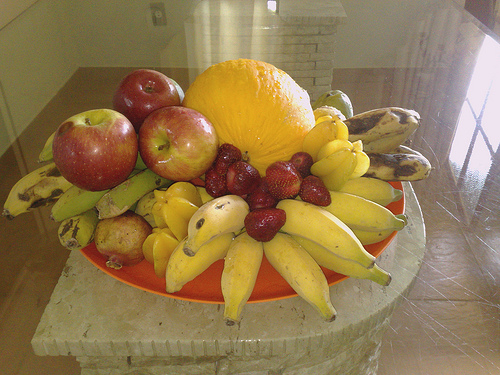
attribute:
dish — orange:
[79, 177, 408, 309]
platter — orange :
[148, 271, 220, 304]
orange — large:
[189, 83, 312, 193]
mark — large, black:
[344, 111, 382, 135]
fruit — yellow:
[341, 108, 418, 145]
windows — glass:
[441, 28, 499, 229]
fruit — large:
[192, 63, 305, 147]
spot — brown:
[187, 199, 221, 254]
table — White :
[30, 152, 433, 373]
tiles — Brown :
[389, 246, 499, 373]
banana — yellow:
[181, 192, 246, 257]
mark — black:
[194, 216, 206, 229]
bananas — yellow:
[30, 43, 462, 334]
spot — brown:
[54, 114, 82, 138]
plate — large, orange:
[79, 175, 408, 303]